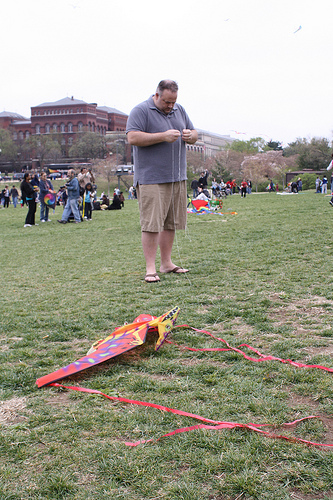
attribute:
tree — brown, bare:
[239, 147, 295, 186]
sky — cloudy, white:
[2, 0, 331, 121]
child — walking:
[83, 183, 97, 219]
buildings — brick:
[3, 99, 265, 204]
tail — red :
[102, 384, 309, 466]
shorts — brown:
[133, 179, 188, 233]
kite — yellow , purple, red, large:
[31, 308, 331, 450]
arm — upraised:
[200, 171, 209, 178]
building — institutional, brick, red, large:
[0, 91, 134, 176]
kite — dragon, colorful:
[37, 306, 182, 388]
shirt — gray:
[126, 97, 197, 189]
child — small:
[29, 170, 39, 196]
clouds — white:
[150, 20, 237, 69]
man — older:
[123, 78, 199, 282]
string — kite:
[170, 127, 194, 290]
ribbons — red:
[160, 136, 196, 194]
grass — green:
[240, 230, 279, 268]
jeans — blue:
[35, 170, 57, 223]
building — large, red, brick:
[0, 94, 205, 172]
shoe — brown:
[161, 263, 189, 275]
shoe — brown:
[143, 271, 161, 284]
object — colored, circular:
[41, 193, 58, 208]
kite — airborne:
[240, 13, 306, 178]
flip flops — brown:
[142, 265, 186, 281]